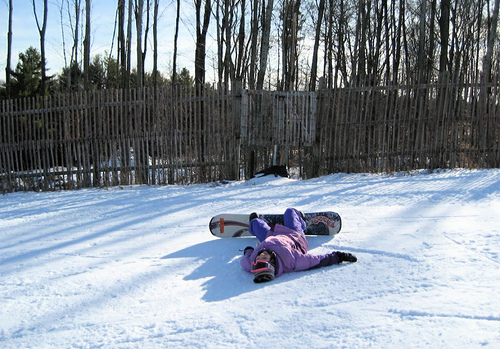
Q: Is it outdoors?
A: Yes, it is outdoors.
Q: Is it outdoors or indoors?
A: It is outdoors.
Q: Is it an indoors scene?
A: No, it is outdoors.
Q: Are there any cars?
A: No, there are no cars.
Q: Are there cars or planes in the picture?
A: No, there are no cars or planes.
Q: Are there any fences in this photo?
A: Yes, there is a fence.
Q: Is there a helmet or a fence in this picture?
A: Yes, there is a fence.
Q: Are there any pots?
A: No, there are no pots.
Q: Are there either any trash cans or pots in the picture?
A: No, there are no pots or trash cans.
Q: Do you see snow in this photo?
A: Yes, there is snow.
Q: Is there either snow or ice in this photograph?
A: Yes, there is snow.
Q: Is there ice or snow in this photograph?
A: Yes, there is snow.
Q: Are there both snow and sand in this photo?
A: No, there is snow but no sand.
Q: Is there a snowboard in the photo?
A: Yes, there is a snowboard.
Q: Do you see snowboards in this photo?
A: Yes, there is a snowboard.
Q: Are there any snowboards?
A: Yes, there is a snowboard.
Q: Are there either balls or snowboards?
A: Yes, there is a snowboard.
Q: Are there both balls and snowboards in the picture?
A: No, there is a snowboard but no balls.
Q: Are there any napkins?
A: No, there are no napkins.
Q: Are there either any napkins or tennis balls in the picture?
A: No, there are no napkins or tennis balls.